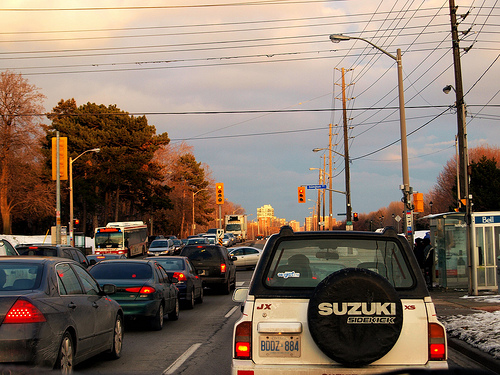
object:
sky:
[0, 6, 498, 198]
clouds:
[3, 1, 164, 52]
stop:
[472, 212, 499, 294]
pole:
[448, 0, 469, 212]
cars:
[0, 256, 126, 375]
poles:
[397, 48, 413, 248]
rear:
[230, 225, 449, 375]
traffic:
[0, 189, 498, 375]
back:
[230, 226, 450, 375]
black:
[306, 267, 404, 366]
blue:
[0, 267, 118, 352]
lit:
[5, 296, 45, 324]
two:
[211, 182, 305, 206]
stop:
[97, 241, 236, 299]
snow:
[459, 312, 499, 349]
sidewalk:
[126, 335, 497, 375]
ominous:
[14, 29, 343, 89]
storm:
[74, 88, 385, 130]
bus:
[91, 221, 149, 258]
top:
[100, 228, 119, 232]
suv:
[180, 245, 238, 293]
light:
[221, 263, 227, 273]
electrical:
[4, 12, 499, 118]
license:
[259, 333, 301, 357]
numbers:
[258, 336, 299, 357]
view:
[0, 118, 500, 375]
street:
[82, 164, 280, 375]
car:
[84, 259, 182, 331]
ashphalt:
[132, 318, 224, 375]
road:
[80, 259, 217, 375]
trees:
[4, 70, 240, 228]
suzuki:
[318, 301, 397, 325]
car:
[228, 225, 450, 375]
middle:
[148, 261, 234, 373]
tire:
[319, 265, 399, 375]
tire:
[306, 267, 404, 365]